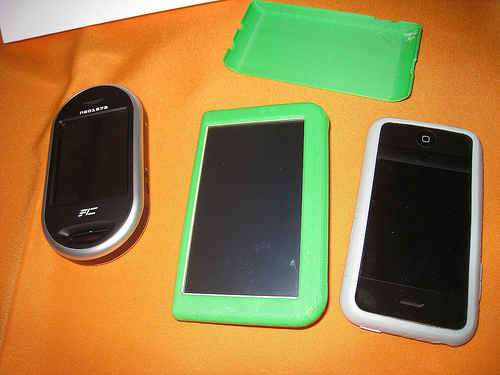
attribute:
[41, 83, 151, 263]
phone — grey, silver, old, black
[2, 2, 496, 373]
cloth — orange, wooden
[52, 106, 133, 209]
screen — off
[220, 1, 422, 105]
cover — green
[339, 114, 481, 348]
phone — white, black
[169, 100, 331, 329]
phone — green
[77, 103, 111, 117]
letters — white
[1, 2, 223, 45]
paper — white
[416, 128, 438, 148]
button — round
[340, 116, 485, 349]
case — white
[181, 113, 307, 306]
screen — dirty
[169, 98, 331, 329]
case — green